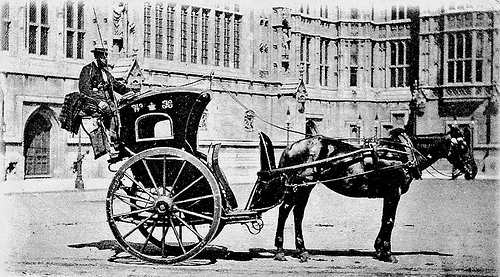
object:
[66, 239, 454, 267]
shadow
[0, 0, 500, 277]
picture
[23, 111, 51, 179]
door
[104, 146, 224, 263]
wheel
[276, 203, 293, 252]
legs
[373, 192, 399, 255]
legs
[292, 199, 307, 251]
legs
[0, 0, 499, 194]
building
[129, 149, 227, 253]
wheel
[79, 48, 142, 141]
man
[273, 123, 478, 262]
brown horse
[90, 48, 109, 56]
hat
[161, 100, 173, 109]
numbers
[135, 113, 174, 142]
window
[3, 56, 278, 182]
wall.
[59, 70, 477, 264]
carriage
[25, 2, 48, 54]
window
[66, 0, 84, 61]
window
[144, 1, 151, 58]
window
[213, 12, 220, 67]
window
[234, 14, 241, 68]
window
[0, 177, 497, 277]
floor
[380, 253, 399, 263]
hoof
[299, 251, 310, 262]
hoof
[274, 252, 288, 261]
hoof